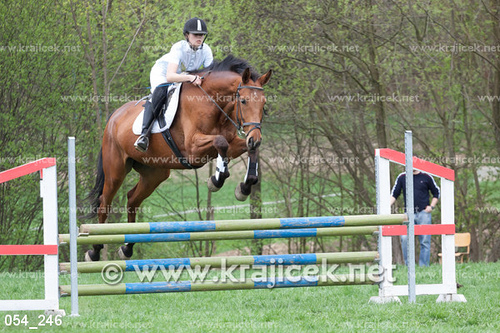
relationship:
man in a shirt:
[390, 152, 441, 267] [392, 159, 435, 212]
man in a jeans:
[390, 152, 441, 267] [404, 209, 430, 272]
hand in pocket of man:
[420, 200, 442, 215] [390, 152, 441, 267]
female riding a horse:
[137, 16, 214, 151] [78, 54, 273, 261]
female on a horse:
[137, 16, 214, 151] [89, 62, 279, 263]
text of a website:
[99, 256, 399, 285] [117, 256, 402, 294]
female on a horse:
[137, 16, 214, 151] [152, 67, 270, 192]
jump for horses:
[21, 139, 466, 299] [87, 75, 292, 206]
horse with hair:
[87, 61, 293, 223] [203, 53, 261, 83]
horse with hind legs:
[78, 54, 273, 261] [83, 135, 172, 262]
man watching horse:
[390, 152, 441, 267] [78, 54, 273, 261]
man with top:
[386, 145, 441, 271] [392, 168, 442, 214]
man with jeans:
[386, 145, 441, 271] [399, 208, 435, 270]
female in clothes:
[132, 8, 237, 146] [119, 39, 202, 86]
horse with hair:
[78, 54, 273, 261] [92, 57, 284, 191]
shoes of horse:
[203, 173, 251, 202] [208, 170, 271, 202]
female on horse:
[137, 16, 214, 151] [65, 40, 300, 262]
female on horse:
[137, 16, 214, 151] [78, 54, 273, 261]